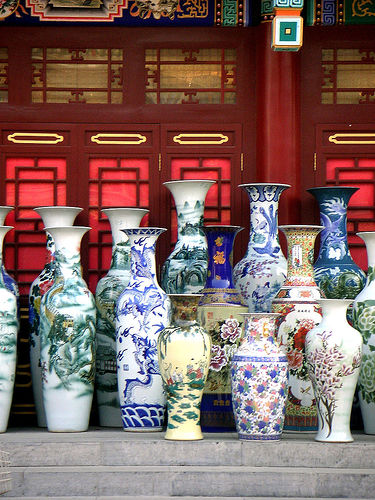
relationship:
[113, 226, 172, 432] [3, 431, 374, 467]
vase on stand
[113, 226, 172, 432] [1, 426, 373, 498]
vase on stand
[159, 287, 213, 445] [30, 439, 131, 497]
vase on stand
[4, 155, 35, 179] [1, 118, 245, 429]
red section on door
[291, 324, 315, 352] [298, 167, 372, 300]
flower on vase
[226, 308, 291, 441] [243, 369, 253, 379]
vase decorated with flower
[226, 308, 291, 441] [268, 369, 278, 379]
vase decorated with flower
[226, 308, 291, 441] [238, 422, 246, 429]
vase decorated with flower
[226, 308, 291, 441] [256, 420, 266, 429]
vase decorated with flower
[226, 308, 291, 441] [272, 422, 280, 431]
vase decorated with flower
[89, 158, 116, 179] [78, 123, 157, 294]
section on door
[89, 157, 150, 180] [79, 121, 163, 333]
section on door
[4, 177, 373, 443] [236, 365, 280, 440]
vases for flowers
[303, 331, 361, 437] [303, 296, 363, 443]
flowers decorations on vase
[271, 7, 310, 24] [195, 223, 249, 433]
orange decorations on blue vase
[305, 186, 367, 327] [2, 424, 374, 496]
vase on surface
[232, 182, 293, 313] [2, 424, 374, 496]
vase on surface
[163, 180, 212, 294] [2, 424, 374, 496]
vases on surface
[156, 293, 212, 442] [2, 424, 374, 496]
vase on surface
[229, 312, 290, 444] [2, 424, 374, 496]
vase on surface